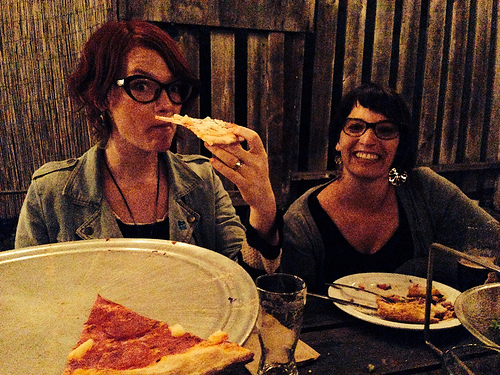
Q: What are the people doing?
A: Eating pizza.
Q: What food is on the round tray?
A: Pizza.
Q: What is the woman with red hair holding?
A: A slice of pizza.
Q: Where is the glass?
A: Next to the pizza tray.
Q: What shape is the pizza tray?
A: Circle.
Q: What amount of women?
A: 2.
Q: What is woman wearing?
A: Glasses.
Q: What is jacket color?
A: Green.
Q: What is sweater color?
A: Grey.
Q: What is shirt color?
A: Black.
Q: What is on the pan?
A: Pizza.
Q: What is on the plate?
A: Food.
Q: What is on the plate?
A: Slice.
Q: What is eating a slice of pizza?
A: The woman.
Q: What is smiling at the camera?
A: The woman.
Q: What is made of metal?
A: Pizza pan.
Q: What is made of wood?
A: The wall.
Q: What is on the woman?
A: Denim jacket.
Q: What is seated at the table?
A: The women.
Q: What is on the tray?
A: The pizza slice.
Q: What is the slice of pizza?
A: Pepperoni.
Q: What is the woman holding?
A: A pizza slice.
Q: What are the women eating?
A: Pizza.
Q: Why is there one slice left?
A: They ate the rest.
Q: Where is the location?
A: Restaurant.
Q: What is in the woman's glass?
A: Nothing.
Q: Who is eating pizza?
A: Two women.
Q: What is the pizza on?
A: Tray.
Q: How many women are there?
A: Two.